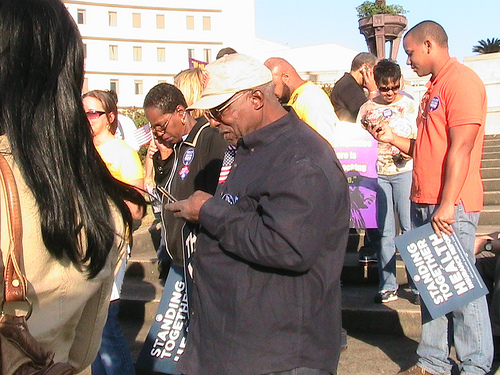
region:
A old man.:
[196, 81, 330, 203]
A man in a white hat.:
[198, 52, 316, 182]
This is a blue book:
[401, 209, 497, 311]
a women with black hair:
[9, 8, 134, 292]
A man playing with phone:
[148, 81, 324, 280]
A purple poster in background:
[326, 109, 413, 259]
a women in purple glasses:
[34, 53, 186, 215]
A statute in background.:
[337, 3, 454, 246]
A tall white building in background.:
[36, 4, 296, 210]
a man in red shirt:
[368, 17, 493, 254]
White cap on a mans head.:
[181, 53, 273, 113]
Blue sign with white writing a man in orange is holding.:
[388, 218, 489, 323]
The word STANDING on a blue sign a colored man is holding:
[148, 278, 190, 357]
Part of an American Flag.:
[214, 141, 236, 186]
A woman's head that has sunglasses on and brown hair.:
[79, 88, 117, 141]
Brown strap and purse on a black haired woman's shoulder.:
[0, 151, 74, 374]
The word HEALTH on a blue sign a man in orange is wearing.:
[426, 231, 467, 298]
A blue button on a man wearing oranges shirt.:
[430, 95, 440, 111]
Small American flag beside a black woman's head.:
[124, 122, 158, 158]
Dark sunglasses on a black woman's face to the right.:
[372, 77, 401, 95]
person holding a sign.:
[406, 30, 493, 362]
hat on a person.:
[188, 54, 289, 133]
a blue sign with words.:
[393, 207, 498, 342]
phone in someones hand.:
[144, 181, 188, 218]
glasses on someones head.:
[137, 118, 179, 137]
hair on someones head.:
[90, 80, 127, 125]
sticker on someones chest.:
[426, 90, 445, 116]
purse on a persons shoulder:
[0, 155, 61, 372]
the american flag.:
[133, 121, 160, 147]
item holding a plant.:
[358, 5, 405, 60]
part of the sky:
[298, 7, 325, 29]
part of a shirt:
[233, 334, 268, 361]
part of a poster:
[143, 330, 165, 355]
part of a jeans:
[443, 317, 467, 349]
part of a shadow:
[355, 331, 388, 351]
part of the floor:
[361, 355, 381, 372]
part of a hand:
[430, 208, 449, 230]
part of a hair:
[58, 174, 99, 211]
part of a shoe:
[396, 351, 416, 373]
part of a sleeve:
[196, 194, 225, 216]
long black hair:
[2, 1, 159, 284]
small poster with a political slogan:
[391, 217, 488, 317]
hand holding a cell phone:
[154, 181, 213, 223]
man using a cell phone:
[329, 49, 379, 124]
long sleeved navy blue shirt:
[196, 104, 353, 371]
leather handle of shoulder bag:
[1, 156, 39, 305]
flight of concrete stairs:
[478, 132, 499, 227]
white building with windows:
[63, 0, 226, 112]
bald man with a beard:
[264, 56, 340, 141]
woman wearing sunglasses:
[79, 88, 144, 250]